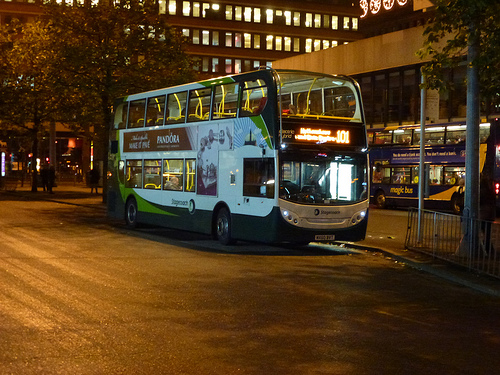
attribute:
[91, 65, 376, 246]
bus — double-decker